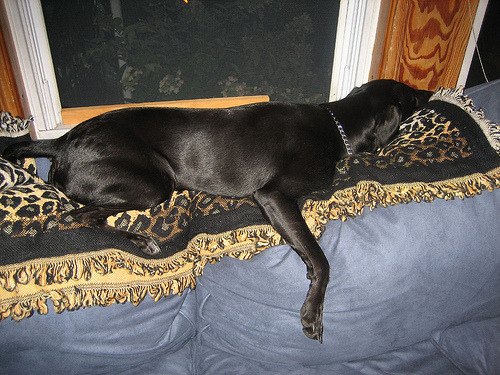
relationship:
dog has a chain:
[5, 79, 434, 342] [326, 103, 354, 159]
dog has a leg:
[5, 79, 434, 342] [257, 194, 330, 341]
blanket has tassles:
[1, 87, 498, 320] [419, 190, 441, 202]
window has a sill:
[4, 2, 379, 145] [329, 2, 389, 100]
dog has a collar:
[5, 79, 434, 342] [328, 106, 352, 158]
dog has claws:
[5, 79, 434, 342] [316, 336, 325, 346]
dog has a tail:
[5, 79, 434, 342] [5, 140, 60, 163]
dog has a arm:
[5, 79, 434, 342] [254, 193, 327, 342]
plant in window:
[49, 3, 328, 108] [4, 2, 379, 145]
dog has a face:
[5, 79, 434, 342] [400, 85, 434, 120]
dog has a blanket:
[5, 79, 434, 342] [1, 87, 498, 320]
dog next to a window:
[5, 79, 434, 342] [4, 2, 379, 145]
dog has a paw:
[5, 79, 434, 342] [300, 302, 327, 340]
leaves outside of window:
[95, 5, 126, 39] [4, 2, 379, 145]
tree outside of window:
[44, 1, 330, 108] [4, 2, 379, 145]